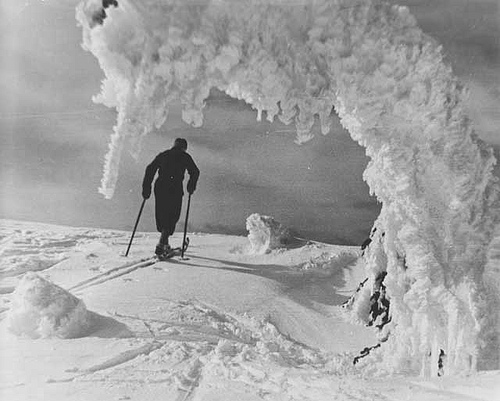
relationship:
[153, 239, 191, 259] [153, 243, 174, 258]
skis on man's feet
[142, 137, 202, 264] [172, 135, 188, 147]
man with dark hair